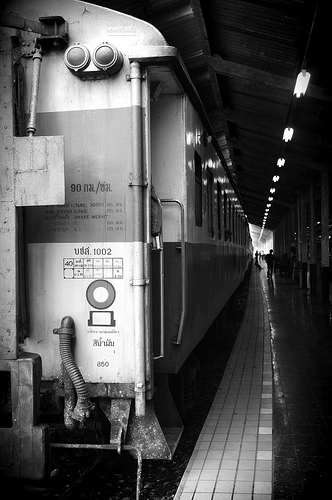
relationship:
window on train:
[193, 146, 205, 230] [0, 2, 253, 498]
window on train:
[204, 165, 215, 244] [0, 2, 253, 498]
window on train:
[216, 179, 223, 242] [0, 2, 253, 498]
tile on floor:
[220, 459, 242, 469] [161, 261, 286, 497]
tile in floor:
[254, 480, 274, 493] [167, 258, 294, 492]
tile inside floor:
[259, 407, 276, 417] [155, 255, 280, 497]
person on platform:
[266, 249, 276, 278] [164, 243, 296, 496]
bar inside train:
[157, 195, 192, 351] [3, 2, 264, 463]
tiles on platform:
[163, 311, 286, 498] [159, 23, 327, 496]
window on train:
[193, 151, 205, 236] [3, 2, 264, 463]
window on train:
[205, 161, 216, 238] [3, 2, 264, 463]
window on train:
[225, 202, 233, 258] [3, 2, 264, 463]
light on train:
[68, 44, 116, 65] [8, 2, 244, 417]